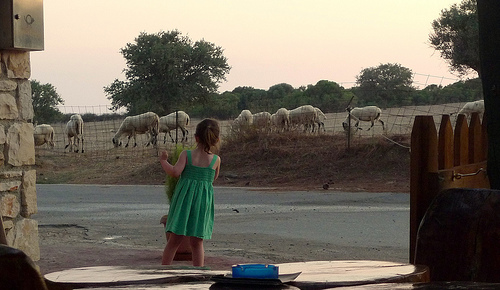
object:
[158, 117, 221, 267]
girl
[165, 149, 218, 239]
dress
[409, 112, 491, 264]
gate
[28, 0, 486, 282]
entrance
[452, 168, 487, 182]
handle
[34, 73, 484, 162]
fence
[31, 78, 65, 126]
tree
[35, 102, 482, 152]
field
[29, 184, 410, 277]
road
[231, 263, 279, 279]
ashtray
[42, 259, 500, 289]
table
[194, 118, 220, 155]
hair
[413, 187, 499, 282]
chair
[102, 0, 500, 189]
trees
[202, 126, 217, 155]
ponytail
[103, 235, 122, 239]
water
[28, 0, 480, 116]
sky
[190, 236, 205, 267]
leg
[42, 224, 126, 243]
dirt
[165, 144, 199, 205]
plant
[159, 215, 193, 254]
flower pot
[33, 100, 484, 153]
flock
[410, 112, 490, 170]
top